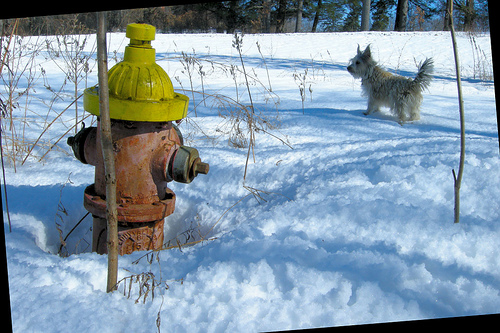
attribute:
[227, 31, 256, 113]
shrubbage — brown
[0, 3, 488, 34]
trees — brown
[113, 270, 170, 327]
leaves — dead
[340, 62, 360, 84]
nose — black 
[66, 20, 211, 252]
fire hydrant — red, yellow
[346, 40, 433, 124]
puppy — little, white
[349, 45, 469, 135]
dog — standing up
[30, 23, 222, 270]
hydrant — yellow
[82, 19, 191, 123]
top — yellow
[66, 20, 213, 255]
hydrant — red, yellow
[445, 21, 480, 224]
twig — wooden, sticking out of ground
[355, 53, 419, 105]
dog — light brown, small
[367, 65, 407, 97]
fur — long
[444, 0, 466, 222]
trunk — skinny